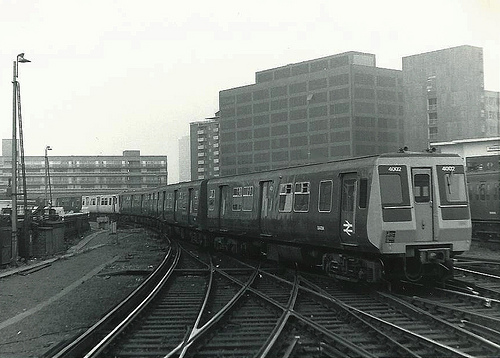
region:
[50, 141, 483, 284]
a very long train near a building.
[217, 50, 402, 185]
a very tall building.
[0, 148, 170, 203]
a tall multi story building.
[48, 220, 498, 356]
train tracks in a train yard.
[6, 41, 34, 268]
a light near train track.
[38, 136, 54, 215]
a light suspended above tracks.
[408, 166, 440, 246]
a door on the front of a train.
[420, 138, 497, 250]
a train on tracks.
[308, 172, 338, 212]
the window on the side of a train.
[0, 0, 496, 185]
a gray hazy sky.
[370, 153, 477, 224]
Back windows of train.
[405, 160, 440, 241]
Backdoor of train.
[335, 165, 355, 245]
Side door of train.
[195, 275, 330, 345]
Black criss crossed train tracks.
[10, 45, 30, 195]
Grey light pole.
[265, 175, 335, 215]
Side windows on train.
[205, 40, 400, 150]
Big building behind train.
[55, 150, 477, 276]
Long multicolor train.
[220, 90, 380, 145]
Windows on the big building behind the train.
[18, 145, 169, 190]
Small brown building behind train.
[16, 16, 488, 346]
Black and white picture.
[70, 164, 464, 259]
Train is running.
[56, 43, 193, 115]
Sky is white color.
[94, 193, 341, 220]
Windows are attached to the sides of the train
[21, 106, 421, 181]
Buildings are found behind the train.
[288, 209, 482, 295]
Train is on track.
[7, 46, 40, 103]
Lights are attached to the pole.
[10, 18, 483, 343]
Day time picture.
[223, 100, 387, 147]
Windows are attached to the building.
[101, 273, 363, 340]
Gravel is between the track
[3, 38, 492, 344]
a black and white picture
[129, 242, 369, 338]
a few train tracks intersecting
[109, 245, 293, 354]
a pair of train tracks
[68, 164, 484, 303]
a long passenger train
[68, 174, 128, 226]
a light colored train car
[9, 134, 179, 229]
a multi story building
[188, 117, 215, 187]
a vertical row of porches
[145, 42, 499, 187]
a few tall buildings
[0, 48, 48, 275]
a tall street light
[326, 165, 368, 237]
a small metal door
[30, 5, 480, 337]
train on one of several tracks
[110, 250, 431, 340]
rails merging into other tracks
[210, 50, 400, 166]
boxy building with rectangular windows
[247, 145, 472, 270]
front of car lighter than sides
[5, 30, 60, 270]
poles with instrument on top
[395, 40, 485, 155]
rectangular building with middle windows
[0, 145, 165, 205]
wide and low building behind train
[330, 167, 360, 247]
symbol on lower part of door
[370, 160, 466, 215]
identifying numbers on top of windows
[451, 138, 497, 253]
part of older car on side of train